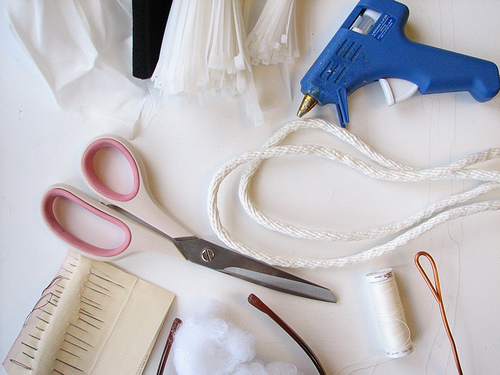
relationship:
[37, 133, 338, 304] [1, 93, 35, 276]
objects on table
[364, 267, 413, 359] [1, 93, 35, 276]
spool on table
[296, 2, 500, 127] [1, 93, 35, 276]
glue gun on table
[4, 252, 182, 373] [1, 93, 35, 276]
needles on table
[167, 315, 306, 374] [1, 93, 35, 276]
cotton on th table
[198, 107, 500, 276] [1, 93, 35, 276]
rope on table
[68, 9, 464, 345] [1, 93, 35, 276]
craft supples on table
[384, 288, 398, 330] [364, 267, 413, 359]
spool of spool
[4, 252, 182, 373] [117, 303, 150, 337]
needles on paper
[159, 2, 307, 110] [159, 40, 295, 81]
plastic ties are in bunch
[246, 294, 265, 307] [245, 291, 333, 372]
edge of eyeglasses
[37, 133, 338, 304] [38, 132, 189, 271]
objects have pink grips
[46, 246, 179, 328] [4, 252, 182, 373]
package of needles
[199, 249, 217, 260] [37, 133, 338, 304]
screw in objects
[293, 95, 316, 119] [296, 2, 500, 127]
tip of glue gun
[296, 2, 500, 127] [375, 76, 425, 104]
glue gun with white trigger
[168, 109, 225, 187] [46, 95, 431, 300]
white surface under objects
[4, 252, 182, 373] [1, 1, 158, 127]
needles on cloth